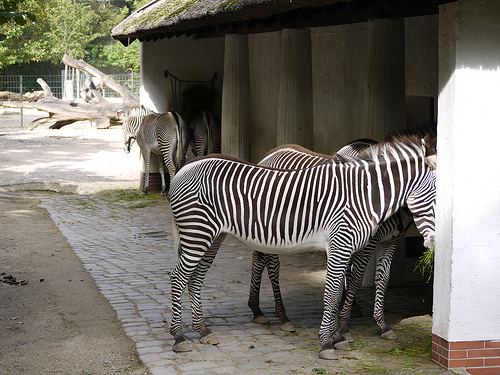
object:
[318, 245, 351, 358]
leg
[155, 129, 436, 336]
zebras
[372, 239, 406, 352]
leg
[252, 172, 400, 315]
zebra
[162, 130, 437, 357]
zebras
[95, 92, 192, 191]
zebra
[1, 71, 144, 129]
green fence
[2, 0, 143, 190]
background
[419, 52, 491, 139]
shadow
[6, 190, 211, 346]
ground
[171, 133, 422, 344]
stripes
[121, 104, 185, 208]
zebra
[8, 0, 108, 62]
leaves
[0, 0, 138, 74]
trees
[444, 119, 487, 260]
wall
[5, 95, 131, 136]
trunk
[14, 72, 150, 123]
trunk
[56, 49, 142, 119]
trunk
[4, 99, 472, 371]
ground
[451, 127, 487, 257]
wall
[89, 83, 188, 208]
zebra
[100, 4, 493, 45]
roof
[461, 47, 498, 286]
wall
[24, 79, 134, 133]
wood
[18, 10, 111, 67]
tree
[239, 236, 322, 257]
belly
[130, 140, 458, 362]
zebra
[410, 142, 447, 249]
head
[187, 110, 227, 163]
zebra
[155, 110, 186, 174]
zebra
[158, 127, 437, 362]
zebra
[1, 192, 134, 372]
paved road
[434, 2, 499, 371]
pillar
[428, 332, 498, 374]
wall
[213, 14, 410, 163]
columns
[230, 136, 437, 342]
zebra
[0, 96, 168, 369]
sidewalk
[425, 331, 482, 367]
brick base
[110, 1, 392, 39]
roof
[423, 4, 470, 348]
wall edge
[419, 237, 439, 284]
food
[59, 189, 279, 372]
walkway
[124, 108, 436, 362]
zebras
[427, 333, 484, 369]
red brick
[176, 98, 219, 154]
shadow